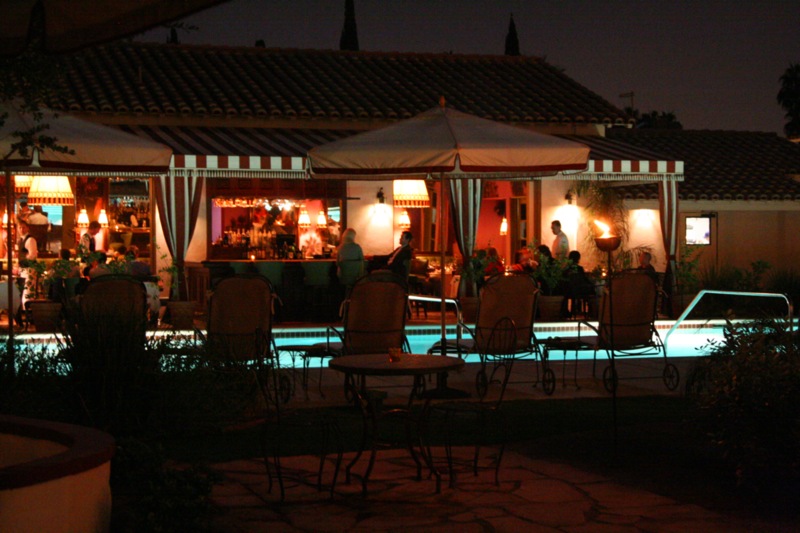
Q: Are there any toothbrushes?
A: No, there are no toothbrushes.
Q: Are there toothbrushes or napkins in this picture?
A: No, there are no toothbrushes or napkins.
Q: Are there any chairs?
A: Yes, there is a chair.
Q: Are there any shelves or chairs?
A: Yes, there is a chair.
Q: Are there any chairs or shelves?
A: Yes, there is a chair.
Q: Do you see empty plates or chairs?
A: Yes, there is an empty chair.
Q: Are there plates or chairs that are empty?
A: Yes, the chair is empty.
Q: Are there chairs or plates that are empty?
A: Yes, the chair is empty.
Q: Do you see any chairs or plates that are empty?
A: Yes, the chair is empty.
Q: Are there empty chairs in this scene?
A: Yes, there is an empty chair.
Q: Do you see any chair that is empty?
A: Yes, there is an empty chair.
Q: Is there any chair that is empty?
A: Yes, there is an empty chair.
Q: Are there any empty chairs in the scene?
A: Yes, there is an empty chair.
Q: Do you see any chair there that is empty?
A: Yes, there is a chair that is empty.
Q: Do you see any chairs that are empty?
A: Yes, there is a chair that is empty.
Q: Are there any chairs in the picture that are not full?
A: Yes, there is a empty chair.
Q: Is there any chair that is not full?
A: Yes, there is a empty chair.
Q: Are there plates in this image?
A: No, there are no plates.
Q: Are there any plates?
A: No, there are no plates.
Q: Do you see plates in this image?
A: No, there are no plates.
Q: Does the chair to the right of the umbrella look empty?
A: Yes, the chair is empty.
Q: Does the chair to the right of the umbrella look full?
A: No, the chair is empty.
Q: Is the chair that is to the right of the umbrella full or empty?
A: The chair is empty.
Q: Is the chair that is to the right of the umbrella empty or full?
A: The chair is empty.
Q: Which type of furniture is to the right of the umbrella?
A: The piece of furniture is a chair.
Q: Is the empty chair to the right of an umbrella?
A: Yes, the chair is to the right of an umbrella.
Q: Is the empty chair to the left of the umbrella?
A: No, the chair is to the right of the umbrella.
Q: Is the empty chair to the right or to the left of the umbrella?
A: The chair is to the right of the umbrella.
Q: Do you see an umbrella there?
A: Yes, there is an umbrella.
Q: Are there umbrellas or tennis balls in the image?
A: Yes, there is an umbrella.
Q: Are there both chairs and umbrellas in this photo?
A: Yes, there are both an umbrella and a chair.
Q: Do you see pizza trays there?
A: No, there are no pizza trays.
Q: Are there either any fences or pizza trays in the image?
A: No, there are no pizza trays or fences.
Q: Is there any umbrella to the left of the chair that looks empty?
A: Yes, there is an umbrella to the left of the chair.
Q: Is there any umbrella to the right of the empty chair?
A: No, the umbrella is to the left of the chair.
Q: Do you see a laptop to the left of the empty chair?
A: No, there is an umbrella to the left of the chair.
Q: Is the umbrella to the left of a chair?
A: Yes, the umbrella is to the left of a chair.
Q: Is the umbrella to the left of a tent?
A: No, the umbrella is to the left of a chair.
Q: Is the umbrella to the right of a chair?
A: No, the umbrella is to the left of a chair.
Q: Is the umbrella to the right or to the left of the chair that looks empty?
A: The umbrella is to the left of the chair.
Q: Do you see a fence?
A: No, there are no fences.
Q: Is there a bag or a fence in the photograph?
A: No, there are no fences or bags.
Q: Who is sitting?
A: The people are sitting.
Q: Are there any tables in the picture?
A: Yes, there is a table.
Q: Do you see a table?
A: Yes, there is a table.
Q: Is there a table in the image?
A: Yes, there is a table.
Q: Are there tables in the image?
A: Yes, there is a table.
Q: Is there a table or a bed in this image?
A: Yes, there is a table.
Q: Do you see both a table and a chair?
A: Yes, there are both a table and a chair.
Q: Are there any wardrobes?
A: No, there are no wardrobes.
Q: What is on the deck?
A: The table is on the deck.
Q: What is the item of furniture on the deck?
A: The piece of furniture is a table.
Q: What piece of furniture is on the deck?
A: The piece of furniture is a table.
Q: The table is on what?
A: The table is on the deck.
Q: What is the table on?
A: The table is on the deck.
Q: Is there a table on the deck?
A: Yes, there is a table on the deck.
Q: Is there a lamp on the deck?
A: No, there is a table on the deck.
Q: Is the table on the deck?
A: Yes, the table is on the deck.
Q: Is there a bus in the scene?
A: No, there are no buses.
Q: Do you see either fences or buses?
A: No, there are no buses or fences.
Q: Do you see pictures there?
A: No, there are no pictures.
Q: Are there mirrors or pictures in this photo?
A: No, there are no pictures or mirrors.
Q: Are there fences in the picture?
A: No, there are no fences.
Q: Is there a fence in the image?
A: No, there are no fences.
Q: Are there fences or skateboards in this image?
A: No, there are no fences or skateboards.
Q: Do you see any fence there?
A: No, there are no fences.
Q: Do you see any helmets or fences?
A: No, there are no fences or helmets.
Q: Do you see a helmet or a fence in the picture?
A: No, there are no fences or helmets.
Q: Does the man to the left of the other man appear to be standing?
A: Yes, the man is standing.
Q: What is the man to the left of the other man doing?
A: The man is standing.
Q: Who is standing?
A: The man is standing.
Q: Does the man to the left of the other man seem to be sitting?
A: No, the man is standing.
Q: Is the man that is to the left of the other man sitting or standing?
A: The man is standing.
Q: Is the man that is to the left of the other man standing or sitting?
A: The man is standing.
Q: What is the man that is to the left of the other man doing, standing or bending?
A: The man is standing.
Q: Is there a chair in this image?
A: Yes, there is a chair.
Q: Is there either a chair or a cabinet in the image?
A: Yes, there is a chair.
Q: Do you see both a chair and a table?
A: Yes, there are both a chair and a table.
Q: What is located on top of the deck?
A: The chair is on top of the deck.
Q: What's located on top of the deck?
A: The chair is on top of the deck.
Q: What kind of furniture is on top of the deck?
A: The piece of furniture is a chair.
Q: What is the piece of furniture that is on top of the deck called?
A: The piece of furniture is a chair.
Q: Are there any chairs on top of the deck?
A: Yes, there is a chair on top of the deck.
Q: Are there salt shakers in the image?
A: No, there are no salt shakers.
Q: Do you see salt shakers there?
A: No, there are no salt shakers.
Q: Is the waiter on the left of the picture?
A: Yes, the waiter is on the left of the image.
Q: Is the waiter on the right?
A: No, the waiter is on the left of the image.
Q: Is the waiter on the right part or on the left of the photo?
A: The waiter is on the left of the image.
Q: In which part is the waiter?
A: The waiter is on the left of the image.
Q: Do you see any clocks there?
A: No, there are no clocks.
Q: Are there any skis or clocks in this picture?
A: No, there are no clocks or skis.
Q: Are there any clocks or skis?
A: No, there are no clocks or skis.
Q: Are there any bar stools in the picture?
A: No, there are no bar stools.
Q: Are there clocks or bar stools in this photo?
A: No, there are no bar stools or clocks.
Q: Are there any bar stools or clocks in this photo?
A: No, there are no bar stools or clocks.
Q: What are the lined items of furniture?
A: The pieces of furniture are chairs.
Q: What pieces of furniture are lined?
A: The pieces of furniture are chairs.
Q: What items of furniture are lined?
A: The pieces of furniture are chairs.